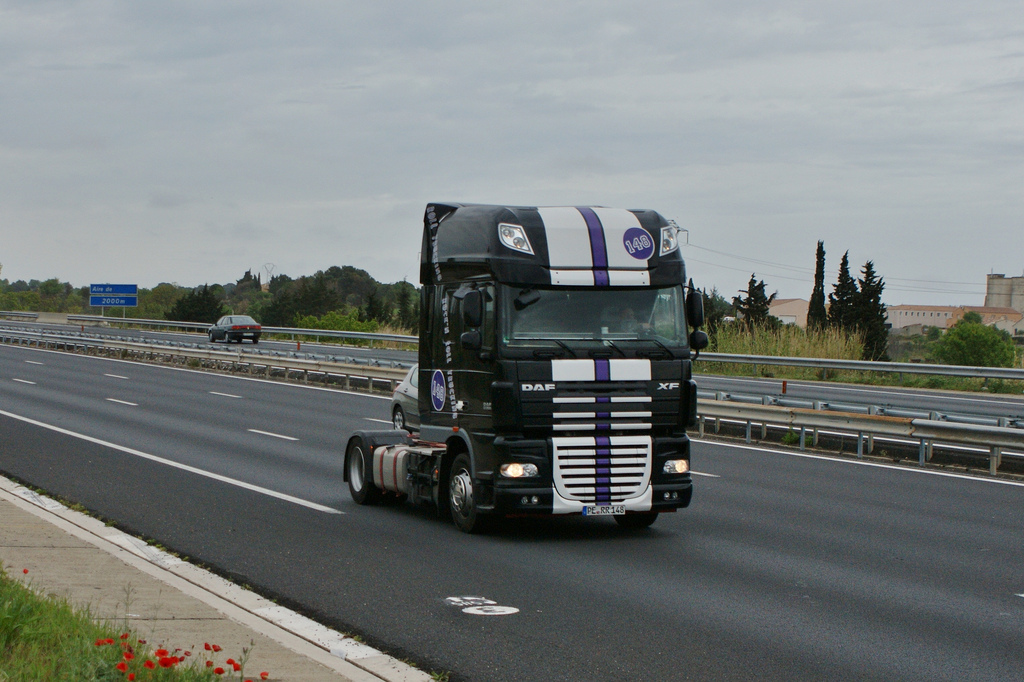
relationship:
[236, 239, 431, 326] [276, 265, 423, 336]
tree in tree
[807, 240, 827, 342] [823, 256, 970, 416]
tree in woods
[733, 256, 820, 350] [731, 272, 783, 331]
tree in tree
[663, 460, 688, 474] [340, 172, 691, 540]
headlight on truck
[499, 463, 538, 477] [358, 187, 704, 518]
headlight on truck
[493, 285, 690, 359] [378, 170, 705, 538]
cab on truck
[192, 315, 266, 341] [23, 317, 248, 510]
car on highway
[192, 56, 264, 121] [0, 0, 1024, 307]
clouds in clouds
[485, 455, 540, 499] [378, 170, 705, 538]
headlight of truck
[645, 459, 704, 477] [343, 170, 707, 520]
headlight of truck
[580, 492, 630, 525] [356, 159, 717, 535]
plate of truck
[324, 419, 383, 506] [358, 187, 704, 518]
tire of truck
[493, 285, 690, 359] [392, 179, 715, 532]
cab of truck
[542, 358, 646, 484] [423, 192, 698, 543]
grill of truck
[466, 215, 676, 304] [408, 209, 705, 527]
cab of truck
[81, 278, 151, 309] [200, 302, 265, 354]
sign in front of car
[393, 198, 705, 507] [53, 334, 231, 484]
truck traveling down road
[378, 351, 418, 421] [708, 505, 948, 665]
vehicle traveling down road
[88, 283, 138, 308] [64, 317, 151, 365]
sign near rail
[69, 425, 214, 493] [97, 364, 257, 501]
line on road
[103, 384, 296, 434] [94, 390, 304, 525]
lines painted on road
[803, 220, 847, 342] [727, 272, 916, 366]
tree in a field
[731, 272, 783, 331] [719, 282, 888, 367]
tree in a field